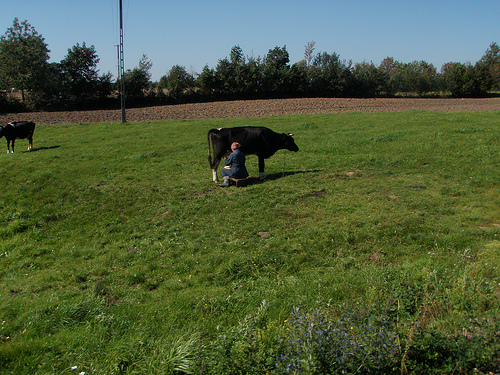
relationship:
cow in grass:
[207, 126, 300, 180] [4, 108, 500, 374]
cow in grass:
[2, 119, 37, 151] [4, 108, 500, 374]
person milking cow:
[220, 139, 249, 188] [207, 126, 300, 180]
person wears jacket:
[220, 139, 249, 188] [225, 151, 247, 175]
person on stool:
[220, 139, 249, 188] [228, 175, 248, 188]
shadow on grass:
[239, 168, 321, 187] [4, 117, 484, 374]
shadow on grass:
[26, 144, 58, 153] [4, 117, 484, 374]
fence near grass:
[2, 89, 380, 102] [4, 108, 500, 374]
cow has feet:
[207, 126, 300, 180] [210, 169, 269, 183]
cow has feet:
[2, 119, 37, 151] [4, 145, 34, 154]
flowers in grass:
[263, 289, 432, 373] [4, 108, 500, 374]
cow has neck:
[207, 126, 300, 180] [278, 132, 291, 151]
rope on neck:
[282, 135, 290, 180] [278, 132, 291, 151]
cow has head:
[207, 126, 300, 180] [282, 130, 301, 154]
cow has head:
[2, 119, 37, 151] [0, 125, 6, 139]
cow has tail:
[207, 126, 300, 180] [205, 127, 220, 166]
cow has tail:
[2, 119, 37, 151] [30, 124, 36, 139]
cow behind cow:
[2, 119, 37, 151] [207, 126, 300, 180]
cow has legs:
[207, 126, 300, 180] [258, 156, 268, 184]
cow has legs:
[207, 126, 300, 180] [211, 154, 221, 183]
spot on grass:
[256, 229, 271, 240] [4, 117, 484, 374]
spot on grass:
[346, 169, 354, 177] [4, 117, 484, 374]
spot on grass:
[388, 194, 398, 202] [4, 117, 484, 374]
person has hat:
[220, 139, 249, 188] [230, 140, 243, 152]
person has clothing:
[220, 139, 249, 188] [220, 149, 248, 181]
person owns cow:
[220, 139, 249, 188] [207, 126, 300, 180]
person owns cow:
[220, 139, 249, 188] [2, 119, 37, 151]